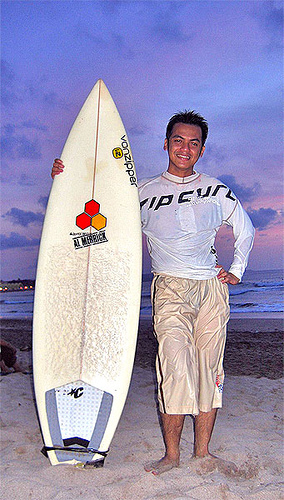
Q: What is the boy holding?
A: A surfboard.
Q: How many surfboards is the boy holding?
A: One.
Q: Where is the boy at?
A: The beach.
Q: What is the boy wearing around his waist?
A: Shorts.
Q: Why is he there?
A: Fun.